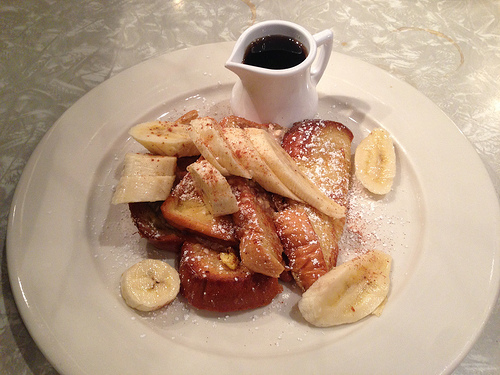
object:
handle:
[307, 29, 332, 88]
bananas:
[111, 110, 397, 328]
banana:
[297, 248, 391, 329]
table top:
[408, 10, 482, 93]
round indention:
[85, 81, 432, 363]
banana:
[222, 128, 345, 221]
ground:
[357, 107, 384, 126]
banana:
[353, 126, 398, 197]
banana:
[118, 255, 183, 314]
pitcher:
[225, 18, 335, 118]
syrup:
[252, 36, 296, 69]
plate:
[6, 42, 499, 373]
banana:
[110, 177, 174, 202]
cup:
[224, 19, 337, 129]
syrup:
[241, 32, 308, 68]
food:
[185, 159, 237, 217]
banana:
[123, 154, 175, 178]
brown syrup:
[180, 232, 283, 312]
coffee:
[250, 35, 305, 67]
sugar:
[315, 189, 400, 256]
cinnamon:
[340, 172, 410, 267]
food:
[266, 118, 355, 243]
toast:
[206, 100, 351, 282]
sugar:
[297, 127, 354, 184]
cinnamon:
[208, 118, 251, 167]